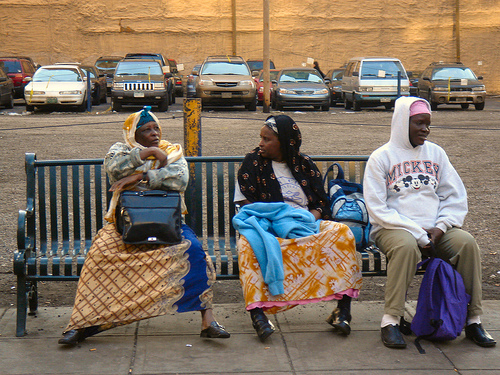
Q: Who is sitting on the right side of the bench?
A: A woman.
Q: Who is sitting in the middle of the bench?
A: A woman.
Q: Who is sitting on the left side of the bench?
A: A woman.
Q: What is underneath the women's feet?
A: Grey sidewalk.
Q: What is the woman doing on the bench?
A: Sitting.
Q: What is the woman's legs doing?
A: Spread open.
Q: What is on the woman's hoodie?
A: Mickey mouse.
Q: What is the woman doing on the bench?
A: Sitting.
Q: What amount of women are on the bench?
A: Three.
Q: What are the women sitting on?
A: A bench.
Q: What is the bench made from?
A: Metal.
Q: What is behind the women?
A: Parked vehicles.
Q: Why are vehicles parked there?
A: It is a parking lot.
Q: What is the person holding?
A: Black bag.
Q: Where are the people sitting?
A: On a bench.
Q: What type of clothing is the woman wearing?
A: A dress.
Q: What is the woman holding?
A: A shirt.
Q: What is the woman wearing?
A: A dress.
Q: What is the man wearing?
A: A gray hoodie.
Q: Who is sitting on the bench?
A: Three people.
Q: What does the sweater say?
A: Mickey.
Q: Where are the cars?
A: Background.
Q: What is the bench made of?
A: Metal.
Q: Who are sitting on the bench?
A: Three women.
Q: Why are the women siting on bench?
A: Resting.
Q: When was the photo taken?
A: Daylight.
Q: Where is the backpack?
A: On ground.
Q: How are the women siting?
A: With legs spread apart.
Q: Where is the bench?
A: On sidewalk.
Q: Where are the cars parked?
A: Background.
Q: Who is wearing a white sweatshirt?
A: Woman at the right.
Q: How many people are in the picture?
A: Three.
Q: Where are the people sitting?
A: On the bench.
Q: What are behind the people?
A: Automobiles.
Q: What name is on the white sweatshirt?
A: Mickey.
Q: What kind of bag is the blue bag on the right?
A: A bookbag.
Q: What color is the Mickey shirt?
A: White.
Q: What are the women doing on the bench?
A: Sitting.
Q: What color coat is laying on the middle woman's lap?
A: Blue.